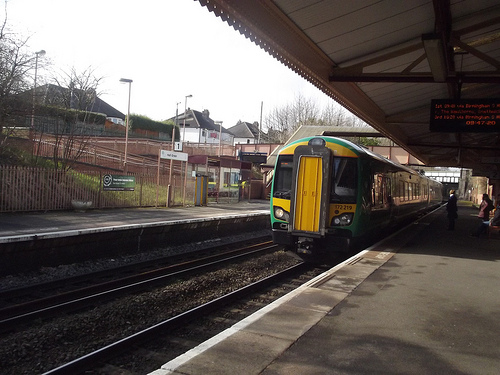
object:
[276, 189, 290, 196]
wiper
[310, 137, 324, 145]
light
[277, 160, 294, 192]
window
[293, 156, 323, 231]
door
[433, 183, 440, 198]
window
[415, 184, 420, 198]
window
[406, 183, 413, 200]
window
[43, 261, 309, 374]
railway track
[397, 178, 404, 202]
window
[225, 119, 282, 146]
building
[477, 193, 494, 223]
woman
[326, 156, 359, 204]
right window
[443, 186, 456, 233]
man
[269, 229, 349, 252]
bumper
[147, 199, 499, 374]
platform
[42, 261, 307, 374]
track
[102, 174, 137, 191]
banner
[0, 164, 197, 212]
fence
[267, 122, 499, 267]
train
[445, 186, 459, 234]
person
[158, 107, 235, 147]
building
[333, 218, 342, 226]
headlight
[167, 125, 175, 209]
pole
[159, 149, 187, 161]
posting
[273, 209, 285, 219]
light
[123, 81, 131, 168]
light pole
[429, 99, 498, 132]
sign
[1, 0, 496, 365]
station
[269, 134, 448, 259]
train